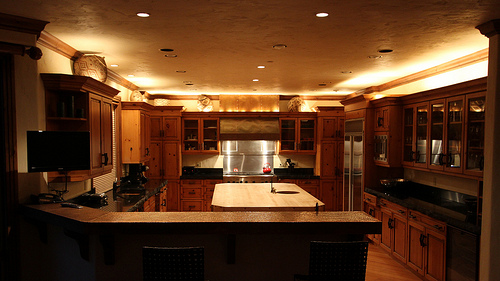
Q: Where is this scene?
A: Kitchen.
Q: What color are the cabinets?
A: Brown.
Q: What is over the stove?
A: Hood.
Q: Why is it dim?
A: No one is there.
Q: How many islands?
A: 1.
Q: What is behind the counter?
A: Island.